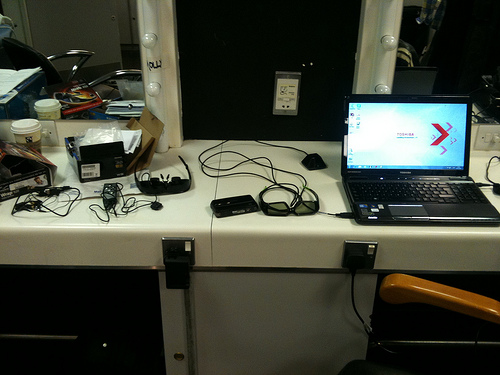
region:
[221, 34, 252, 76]
part of a surface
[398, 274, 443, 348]
part of a handle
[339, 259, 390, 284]
part of a socket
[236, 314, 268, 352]
part of a sutface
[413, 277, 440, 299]
part of a handle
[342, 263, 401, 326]
par tof a wire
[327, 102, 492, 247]
A laptop on the table.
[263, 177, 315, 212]
A pair of sunglasses on the table.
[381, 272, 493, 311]
The chair has a wooden arm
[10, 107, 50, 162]
A cup of coffee on the desk.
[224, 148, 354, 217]
Black cord connected to laptop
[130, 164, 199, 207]
Glare glasses on the desk.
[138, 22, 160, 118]
Two round bulb on the wall.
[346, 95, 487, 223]
The laptop is screen is on.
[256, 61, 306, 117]
A gray box on the wall.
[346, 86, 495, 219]
The laptop keyboard is black.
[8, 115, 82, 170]
Coffee cup on counter top.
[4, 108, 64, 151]
White lid on coffee cup.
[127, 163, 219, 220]
Black sunglasses sitting on table.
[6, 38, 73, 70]
Black back on chair.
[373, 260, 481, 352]
Wood armrest on chair.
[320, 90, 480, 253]
Black laptop sitting on counter.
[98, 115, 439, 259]
Counter top is white in color.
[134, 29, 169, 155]
Light bulbs coming out of wall.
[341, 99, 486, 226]
Laptop is turned on.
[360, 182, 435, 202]
Buttons on computer are black.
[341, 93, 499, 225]
A black laptop.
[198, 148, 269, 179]
Part of a black wire.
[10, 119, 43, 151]
A white coffee cup.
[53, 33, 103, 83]
Part of a mirror.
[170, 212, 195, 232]
Part of the table.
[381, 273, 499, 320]
The arm of a chair.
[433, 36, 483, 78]
Part of a mirror.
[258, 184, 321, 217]
A pair of black sunglasses.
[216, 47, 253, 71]
Part of the wall.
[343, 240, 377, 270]
A silver plug in.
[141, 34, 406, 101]
four white bulbs on wall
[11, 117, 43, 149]
coffee cup with lid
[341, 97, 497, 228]
open black laptop on table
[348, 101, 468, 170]
glowing image on laptop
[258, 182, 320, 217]
black sunglasses on table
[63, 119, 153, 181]
open black box with plastic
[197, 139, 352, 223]
black wire of laptop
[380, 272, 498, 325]
wood arm of chair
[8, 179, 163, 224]
black wires of electronics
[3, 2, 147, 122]
image in mirror on wall